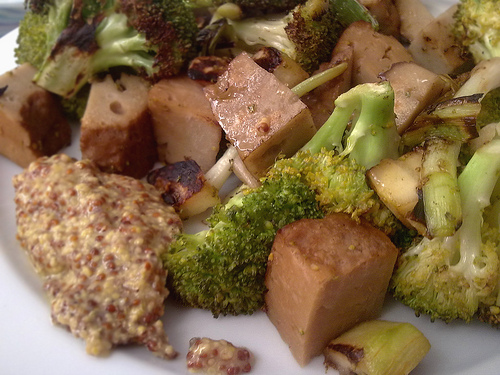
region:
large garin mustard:
[16, 154, 251, 373]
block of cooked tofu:
[268, 209, 397, 366]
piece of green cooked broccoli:
[168, 79, 410, 301]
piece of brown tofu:
[199, 47, 304, 175]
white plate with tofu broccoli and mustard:
[3, 0, 498, 370]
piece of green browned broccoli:
[10, 4, 203, 99]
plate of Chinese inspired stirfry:
[7, 1, 498, 361]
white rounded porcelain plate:
[0, 10, 498, 370]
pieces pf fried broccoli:
[370, 58, 498, 332]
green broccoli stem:
[320, 312, 427, 370]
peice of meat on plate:
[285, 235, 392, 342]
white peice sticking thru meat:
[196, 39, 368, 171]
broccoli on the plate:
[192, 168, 271, 295]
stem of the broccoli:
[450, 160, 495, 280]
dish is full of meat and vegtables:
[30, 21, 481, 371]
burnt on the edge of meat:
[13, 88, 75, 143]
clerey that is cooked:
[342, 320, 435, 374]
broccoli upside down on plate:
[330, 78, 407, 170]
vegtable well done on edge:
[133, 14, 182, 77]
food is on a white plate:
[432, 334, 497, 374]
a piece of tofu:
[262, 200, 415, 373]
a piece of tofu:
[277, 211, 397, 356]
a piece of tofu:
[270, 234, 403, 373]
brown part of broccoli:
[116, 4, 186, 104]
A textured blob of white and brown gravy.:
[13, 155, 182, 359]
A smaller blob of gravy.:
[186, 335, 251, 373]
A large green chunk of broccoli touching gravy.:
[167, 163, 317, 314]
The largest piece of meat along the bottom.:
[261, 215, 401, 366]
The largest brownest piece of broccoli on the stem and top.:
[30, 3, 201, 102]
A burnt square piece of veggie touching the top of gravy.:
[146, 155, 220, 215]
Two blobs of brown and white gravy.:
[12, 158, 251, 374]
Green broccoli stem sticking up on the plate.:
[301, 83, 406, 165]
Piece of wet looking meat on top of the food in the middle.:
[203, 52, 314, 176]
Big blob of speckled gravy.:
[13, 155, 177, 360]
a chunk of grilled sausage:
[202, 54, 312, 181]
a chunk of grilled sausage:
[77, 73, 154, 175]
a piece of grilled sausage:
[147, 75, 219, 173]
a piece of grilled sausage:
[377, 64, 449, 134]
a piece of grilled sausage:
[0, 64, 72, 165]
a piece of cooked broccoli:
[167, 81, 401, 320]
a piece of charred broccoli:
[13, 1, 190, 83]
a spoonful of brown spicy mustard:
[12, 134, 183, 355]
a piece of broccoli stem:
[322, 321, 429, 373]